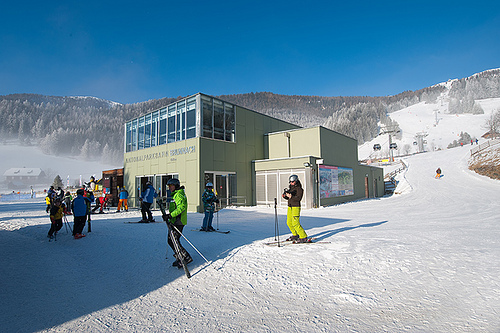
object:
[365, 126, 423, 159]
ski lift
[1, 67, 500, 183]
mountain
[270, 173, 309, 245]
woman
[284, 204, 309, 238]
ski pants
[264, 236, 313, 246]
ski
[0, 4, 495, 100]
skies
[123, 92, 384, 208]
ski lodge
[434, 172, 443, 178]
bright orange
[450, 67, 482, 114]
trees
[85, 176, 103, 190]
blow up penguin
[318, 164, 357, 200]
map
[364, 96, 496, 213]
ski hills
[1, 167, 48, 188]
building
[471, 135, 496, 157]
safety fence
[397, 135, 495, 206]
ski trail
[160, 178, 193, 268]
people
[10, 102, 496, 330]
snow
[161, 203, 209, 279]
ski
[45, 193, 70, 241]
people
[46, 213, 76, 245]
ski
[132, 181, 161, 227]
people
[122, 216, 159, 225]
ski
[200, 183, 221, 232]
people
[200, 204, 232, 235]
ski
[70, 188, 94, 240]
people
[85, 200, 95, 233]
ski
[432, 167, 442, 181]
people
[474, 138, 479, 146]
people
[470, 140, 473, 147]
people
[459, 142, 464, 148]
people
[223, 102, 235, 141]
windows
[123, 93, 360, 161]
second floor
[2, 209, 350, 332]
large shadow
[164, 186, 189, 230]
jacket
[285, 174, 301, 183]
helmet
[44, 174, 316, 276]
skiing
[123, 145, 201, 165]
writing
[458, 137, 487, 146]
three people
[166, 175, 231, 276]
two people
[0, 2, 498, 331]
photo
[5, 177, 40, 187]
logs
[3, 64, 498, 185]
background